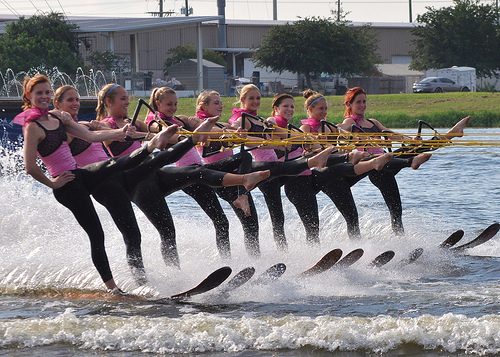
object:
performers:
[294, 80, 435, 246]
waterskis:
[205, 257, 265, 311]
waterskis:
[244, 251, 293, 293]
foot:
[444, 112, 475, 143]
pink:
[89, 146, 107, 158]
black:
[112, 191, 133, 218]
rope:
[157, 120, 499, 155]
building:
[0, 5, 498, 98]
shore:
[0, 86, 499, 136]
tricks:
[0, 43, 498, 308]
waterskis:
[157, 259, 235, 307]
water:
[0, 174, 497, 357]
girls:
[49, 78, 222, 287]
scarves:
[10, 106, 54, 127]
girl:
[6, 69, 183, 299]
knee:
[180, 159, 213, 183]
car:
[401, 72, 473, 97]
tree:
[250, 8, 391, 97]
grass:
[124, 89, 500, 128]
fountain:
[0, 54, 123, 99]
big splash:
[0, 166, 498, 307]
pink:
[53, 150, 79, 171]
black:
[63, 186, 85, 207]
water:
[2, 55, 126, 99]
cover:
[0, 13, 219, 39]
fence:
[338, 71, 431, 97]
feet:
[143, 118, 182, 154]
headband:
[307, 95, 326, 112]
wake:
[0, 300, 500, 349]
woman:
[333, 84, 474, 240]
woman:
[227, 81, 390, 254]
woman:
[96, 80, 272, 271]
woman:
[263, 92, 393, 245]